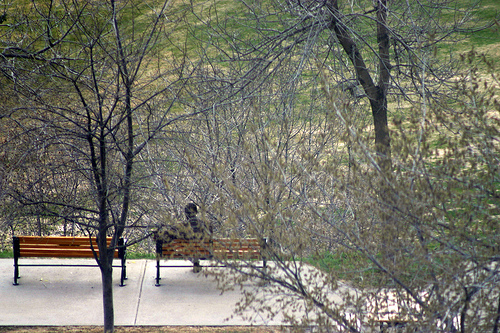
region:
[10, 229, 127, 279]
Tan and black left bench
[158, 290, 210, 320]
Small section of the white sidewalk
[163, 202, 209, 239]
Back view of man sitting down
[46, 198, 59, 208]
Small part of the tree branch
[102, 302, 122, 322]
Oak of the tree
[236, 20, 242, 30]
Small patch of the grass in the ground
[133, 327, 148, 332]
Small patch of dirt in the ground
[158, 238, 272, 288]
Right tan and black bench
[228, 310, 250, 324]
Dead leaves on the tree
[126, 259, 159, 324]
Huge line in the sidewalk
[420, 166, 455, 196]
branches of a tree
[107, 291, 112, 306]
stem of a tree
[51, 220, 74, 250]
back of a bench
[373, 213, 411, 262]
leaves of a tree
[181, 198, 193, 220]
back of a man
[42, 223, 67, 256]
edge of a bench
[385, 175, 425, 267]
stem of a tree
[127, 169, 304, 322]
a man sitting on a wooden bench.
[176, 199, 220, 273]
a man sitting down.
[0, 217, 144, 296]
a wooden bench.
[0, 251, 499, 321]
snow covered ground.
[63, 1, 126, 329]
a tree with not leaves.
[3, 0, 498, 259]
a steep plant covered hillside.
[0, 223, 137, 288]
an empty wooden bench.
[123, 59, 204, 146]
a section of tree branches.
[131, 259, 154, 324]
a crack in the ground.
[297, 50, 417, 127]
a section of a tree trunk.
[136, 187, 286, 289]
A wooden bench with a person on it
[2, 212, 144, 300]
A wooden bench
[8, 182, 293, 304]
Two wooden benches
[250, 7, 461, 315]
A tree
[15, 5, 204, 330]
A tree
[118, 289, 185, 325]
A section of sidewalk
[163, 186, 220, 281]
A man sitting on a bench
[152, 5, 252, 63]
A hillside with grass and some dry areas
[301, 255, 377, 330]
Cement steps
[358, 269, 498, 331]
A wooden bridge type walkway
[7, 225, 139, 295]
Bench on the walkway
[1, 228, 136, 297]
Bench is made of wood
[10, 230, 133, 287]
Wooden bench is brown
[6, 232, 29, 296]
Bench has metal leg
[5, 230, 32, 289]
Leg on bench is iron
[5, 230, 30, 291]
Iron leg on bench is black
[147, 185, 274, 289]
Man sitting on park bench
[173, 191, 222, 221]
Man wearing a black hat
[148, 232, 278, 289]
Park bench is brown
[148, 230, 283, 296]
Park bench is made of wood